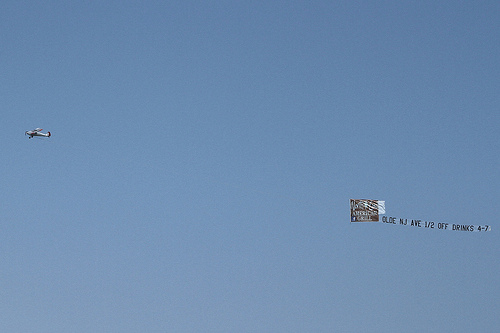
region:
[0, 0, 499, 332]
A plane pulling a banner in the sky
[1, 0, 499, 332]
A clear, cloudless, blue sky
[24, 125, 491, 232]
A small airplane pulling a banner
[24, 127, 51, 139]
A small white airplane flying in the air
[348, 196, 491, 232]
A banner advertising an "American Grill"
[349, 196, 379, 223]
A brown flag with white text indicating the bar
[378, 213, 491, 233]
A white banner advertising a sale on drinks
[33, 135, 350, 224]
A string between the plane and the banner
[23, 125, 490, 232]
A small airplane pulling an advertisement behind it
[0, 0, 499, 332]
A plane in the sky advertising a bar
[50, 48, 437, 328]
the weather is very clear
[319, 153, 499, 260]
this is trailing the plane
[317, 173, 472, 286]
the plane is draging this sign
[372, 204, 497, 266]
the writing is black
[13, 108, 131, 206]
this is a plane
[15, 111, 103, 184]
this is a small plane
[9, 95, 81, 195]
this is a personal plane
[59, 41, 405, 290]
the sky is very light blue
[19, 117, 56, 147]
biplane in flight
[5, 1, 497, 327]
expansive blue sky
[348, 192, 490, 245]
sign fluttering in the air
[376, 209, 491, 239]
letters on clear background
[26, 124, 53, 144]
plane is white and red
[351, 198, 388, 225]
sign is brown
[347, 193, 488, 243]
advertisement flying through the air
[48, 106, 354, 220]
string tying sign to plane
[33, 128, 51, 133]
wing of the biplane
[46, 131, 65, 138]
tail of biplane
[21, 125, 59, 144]
A plane flying way up in the sky.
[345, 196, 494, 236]
A sign being pulled by an airplane.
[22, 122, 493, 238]
A plane pulling a banner.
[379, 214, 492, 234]
An advertisement up in the air.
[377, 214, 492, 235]
A phrase in black letters.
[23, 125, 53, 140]
A primarily white airplane.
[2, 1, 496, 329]
A clear blue sky .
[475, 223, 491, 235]
The numbers 4-7.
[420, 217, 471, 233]
An advertisement for 1/2 off drinks.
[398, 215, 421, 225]
A sign pointing to NJ Ave.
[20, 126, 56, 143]
an airplane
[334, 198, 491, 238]
a banner in the sky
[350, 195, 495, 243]
the banner in the air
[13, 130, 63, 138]
the airplane is pulling the banner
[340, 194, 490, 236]
the banner is long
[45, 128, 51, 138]
tail of the airplane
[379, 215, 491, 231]
words on the banner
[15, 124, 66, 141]
the airplane is being flown in the sky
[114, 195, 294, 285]
the sky is clear